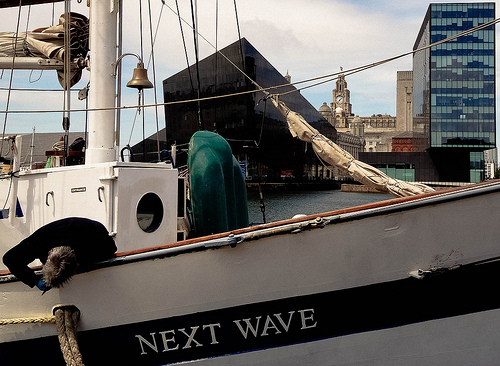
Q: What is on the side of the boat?
A: White writing.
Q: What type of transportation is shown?
A: Boat.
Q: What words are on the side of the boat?
A: Next Wave.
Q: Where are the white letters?
A: In the black stripe.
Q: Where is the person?
A: Hanging over the edge of the boat.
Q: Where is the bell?
A: On the post.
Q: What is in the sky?
A: Clouds.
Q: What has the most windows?
A: Tallest building.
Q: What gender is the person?
A: Male.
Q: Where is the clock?
A: On the tower in the background.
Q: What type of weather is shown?
A: Cloudy.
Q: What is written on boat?
A: Next wave.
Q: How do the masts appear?
A: Rolled up.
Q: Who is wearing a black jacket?
A: Person bending down.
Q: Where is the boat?
A: In water.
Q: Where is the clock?
A: Tall building in background.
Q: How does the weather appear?
A: Sunny with clouds.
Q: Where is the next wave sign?
A: Side of boat.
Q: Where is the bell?
A: Pole in middle of boat.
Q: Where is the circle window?
A: On boat's door.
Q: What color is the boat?
A: White.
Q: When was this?
A: Daytime.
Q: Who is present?
A: Nobody.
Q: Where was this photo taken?
A: Near boat.